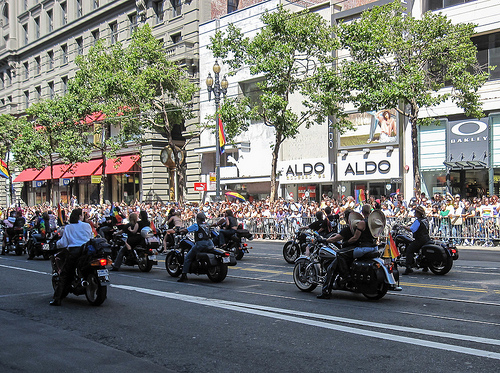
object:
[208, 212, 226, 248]
motorist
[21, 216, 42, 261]
motorist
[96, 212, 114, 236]
motorist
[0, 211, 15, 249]
motorist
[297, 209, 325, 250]
person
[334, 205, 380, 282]
person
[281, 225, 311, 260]
motorcycle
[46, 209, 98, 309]
motorcyclist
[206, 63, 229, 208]
light post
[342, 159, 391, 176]
aldo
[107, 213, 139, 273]
motorcyclist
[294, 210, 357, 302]
motorcyclist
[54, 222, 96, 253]
shirt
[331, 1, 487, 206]
trees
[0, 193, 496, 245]
crowd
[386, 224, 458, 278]
motorcycle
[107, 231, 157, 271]
motorcycle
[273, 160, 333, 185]
sign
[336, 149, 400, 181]
signs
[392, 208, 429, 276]
biker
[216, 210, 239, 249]
people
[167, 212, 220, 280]
biker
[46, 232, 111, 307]
motorcycle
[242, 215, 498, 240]
fence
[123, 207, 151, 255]
woman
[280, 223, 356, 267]
motorcycle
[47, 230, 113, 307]
bike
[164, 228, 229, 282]
bike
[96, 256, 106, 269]
light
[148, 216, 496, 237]
barriers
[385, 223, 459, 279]
motorcycles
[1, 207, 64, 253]
motorcycles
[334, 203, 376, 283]
woman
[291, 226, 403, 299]
motorcycle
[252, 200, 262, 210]
spectators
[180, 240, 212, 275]
pants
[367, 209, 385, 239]
hat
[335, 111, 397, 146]
print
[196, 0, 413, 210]
building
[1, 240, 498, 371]
road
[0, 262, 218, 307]
line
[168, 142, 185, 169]
clock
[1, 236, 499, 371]
street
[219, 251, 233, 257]
light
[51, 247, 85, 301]
pants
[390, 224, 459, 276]
motorcycle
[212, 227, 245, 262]
motorcycle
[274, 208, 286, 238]
people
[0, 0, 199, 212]
buildings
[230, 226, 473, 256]
side walk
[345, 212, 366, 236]
hat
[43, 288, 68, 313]
shoes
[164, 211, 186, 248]
people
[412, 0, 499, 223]
building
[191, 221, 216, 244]
vest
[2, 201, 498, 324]
parade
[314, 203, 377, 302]
couple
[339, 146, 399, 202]
store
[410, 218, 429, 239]
vest